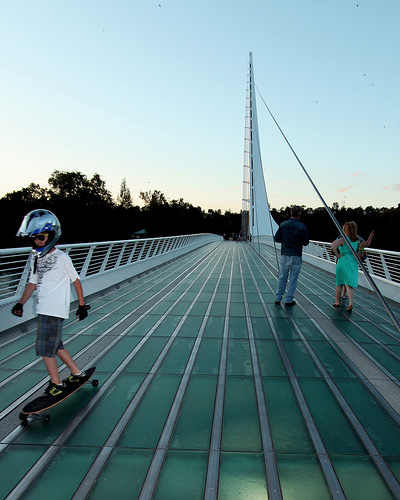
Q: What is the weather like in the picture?
A: It is clear.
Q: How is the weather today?
A: It is clear.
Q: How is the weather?
A: It is clear.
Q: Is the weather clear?
A: Yes, it is clear.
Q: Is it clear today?
A: Yes, it is clear.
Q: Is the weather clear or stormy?
A: It is clear.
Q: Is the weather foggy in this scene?
A: No, it is clear.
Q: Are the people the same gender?
A: No, they are both male and female.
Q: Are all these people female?
A: No, they are both male and female.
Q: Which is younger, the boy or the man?
A: The boy is younger than the man.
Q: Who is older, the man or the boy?
A: The man is older than the boy.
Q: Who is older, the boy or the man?
A: The man is older than the boy.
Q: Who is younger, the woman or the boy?
A: The boy is younger than the woman.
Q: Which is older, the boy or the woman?
A: The woman is older than the boy.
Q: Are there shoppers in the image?
A: No, there are no shoppers.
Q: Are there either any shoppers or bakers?
A: No, there are no shoppers or bakers.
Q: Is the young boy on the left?
A: Yes, the boy is on the left of the image.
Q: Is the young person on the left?
A: Yes, the boy is on the left of the image.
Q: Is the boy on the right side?
A: No, the boy is on the left of the image.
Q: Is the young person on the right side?
A: No, the boy is on the left of the image.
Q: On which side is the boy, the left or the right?
A: The boy is on the left of the image.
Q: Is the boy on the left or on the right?
A: The boy is on the left of the image.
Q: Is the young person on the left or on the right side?
A: The boy is on the left of the image.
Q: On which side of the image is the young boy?
A: The boy is on the left of the image.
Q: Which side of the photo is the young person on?
A: The boy is on the left of the image.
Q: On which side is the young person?
A: The boy is on the left of the image.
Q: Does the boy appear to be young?
A: Yes, the boy is young.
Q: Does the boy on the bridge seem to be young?
A: Yes, the boy is young.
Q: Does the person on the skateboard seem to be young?
A: Yes, the boy is young.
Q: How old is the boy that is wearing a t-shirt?
A: The boy is young.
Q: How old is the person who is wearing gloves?
A: The boy is young.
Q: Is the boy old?
A: No, the boy is young.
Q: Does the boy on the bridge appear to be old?
A: No, the boy is young.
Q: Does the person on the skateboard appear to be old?
A: No, the boy is young.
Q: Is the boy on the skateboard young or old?
A: The boy is young.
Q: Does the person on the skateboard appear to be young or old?
A: The boy is young.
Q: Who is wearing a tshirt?
A: The boy is wearing a tshirt.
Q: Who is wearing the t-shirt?
A: The boy is wearing a tshirt.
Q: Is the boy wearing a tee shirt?
A: Yes, the boy is wearing a tee shirt.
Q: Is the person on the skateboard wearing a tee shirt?
A: Yes, the boy is wearing a tee shirt.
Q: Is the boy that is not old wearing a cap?
A: No, the boy is wearing a tee shirt.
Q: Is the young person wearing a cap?
A: No, the boy is wearing a tee shirt.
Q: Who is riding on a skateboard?
A: The boy is riding on a skateboard.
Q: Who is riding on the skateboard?
A: The boy is riding on a skateboard.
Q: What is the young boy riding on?
A: The boy is riding on a skateboard.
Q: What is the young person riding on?
A: The boy is riding on a skateboard.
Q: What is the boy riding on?
A: The boy is riding on a skateboard.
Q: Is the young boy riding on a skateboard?
A: Yes, the boy is riding on a skateboard.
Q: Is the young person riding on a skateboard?
A: Yes, the boy is riding on a skateboard.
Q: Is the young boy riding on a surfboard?
A: No, the boy is riding on a skateboard.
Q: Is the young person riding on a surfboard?
A: No, the boy is riding on a skateboard.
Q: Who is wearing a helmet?
A: The boy is wearing a helmet.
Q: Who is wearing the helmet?
A: The boy is wearing a helmet.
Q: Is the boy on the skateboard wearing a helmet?
A: Yes, the boy is wearing a helmet.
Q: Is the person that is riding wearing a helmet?
A: Yes, the boy is wearing a helmet.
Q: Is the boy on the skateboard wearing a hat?
A: No, the boy is wearing a helmet.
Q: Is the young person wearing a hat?
A: No, the boy is wearing a helmet.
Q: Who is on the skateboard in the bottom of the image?
A: The boy is on the skateboard.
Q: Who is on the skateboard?
A: The boy is on the skateboard.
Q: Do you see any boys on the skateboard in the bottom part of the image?
A: Yes, there is a boy on the skateboard.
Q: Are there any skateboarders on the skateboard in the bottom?
A: No, there is a boy on the skateboard.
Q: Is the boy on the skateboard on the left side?
A: Yes, the boy is on the skateboard.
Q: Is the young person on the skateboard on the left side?
A: Yes, the boy is on the skateboard.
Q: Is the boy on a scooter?
A: No, the boy is on the skateboard.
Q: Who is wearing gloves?
A: The boy is wearing gloves.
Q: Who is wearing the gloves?
A: The boy is wearing gloves.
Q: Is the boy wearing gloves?
A: Yes, the boy is wearing gloves.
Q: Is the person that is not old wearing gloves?
A: Yes, the boy is wearing gloves.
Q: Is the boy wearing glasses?
A: No, the boy is wearing gloves.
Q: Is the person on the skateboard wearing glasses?
A: No, the boy is wearing gloves.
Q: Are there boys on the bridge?
A: Yes, there is a boy on the bridge.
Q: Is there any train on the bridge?
A: No, there is a boy on the bridge.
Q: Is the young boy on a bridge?
A: Yes, the boy is on a bridge.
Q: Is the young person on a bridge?
A: Yes, the boy is on a bridge.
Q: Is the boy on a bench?
A: No, the boy is on a bridge.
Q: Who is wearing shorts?
A: The boy is wearing shorts.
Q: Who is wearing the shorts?
A: The boy is wearing shorts.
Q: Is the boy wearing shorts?
A: Yes, the boy is wearing shorts.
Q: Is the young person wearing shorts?
A: Yes, the boy is wearing shorts.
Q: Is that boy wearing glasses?
A: No, the boy is wearing shorts.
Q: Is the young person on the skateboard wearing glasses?
A: No, the boy is wearing shorts.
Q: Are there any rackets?
A: No, there are no rackets.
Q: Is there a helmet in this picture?
A: Yes, there is a helmet.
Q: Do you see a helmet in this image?
A: Yes, there is a helmet.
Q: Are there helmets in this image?
A: Yes, there is a helmet.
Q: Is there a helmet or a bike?
A: Yes, there is a helmet.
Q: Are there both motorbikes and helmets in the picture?
A: No, there is a helmet but no motorcycles.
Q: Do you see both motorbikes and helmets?
A: No, there is a helmet but no motorcycles.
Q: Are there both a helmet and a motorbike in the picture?
A: No, there is a helmet but no motorcycles.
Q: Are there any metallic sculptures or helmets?
A: Yes, there is a metal helmet.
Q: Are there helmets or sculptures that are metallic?
A: Yes, the helmet is metallic.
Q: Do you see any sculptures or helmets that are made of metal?
A: Yes, the helmet is made of metal.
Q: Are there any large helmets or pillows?
A: Yes, there is a large helmet.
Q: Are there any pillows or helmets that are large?
A: Yes, the helmet is large.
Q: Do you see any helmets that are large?
A: Yes, there is a large helmet.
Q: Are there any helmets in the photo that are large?
A: Yes, there is a helmet that is large.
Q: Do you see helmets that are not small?
A: Yes, there is a large helmet.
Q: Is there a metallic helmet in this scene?
A: Yes, there is a metal helmet.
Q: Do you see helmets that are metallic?
A: Yes, there is a helmet that is metallic.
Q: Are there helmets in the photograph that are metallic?
A: Yes, there is a helmet that is metallic.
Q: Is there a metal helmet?
A: Yes, there is a helmet that is made of metal.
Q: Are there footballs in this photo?
A: No, there are no footballs.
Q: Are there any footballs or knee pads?
A: No, there are no footballs or knee pads.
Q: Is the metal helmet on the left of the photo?
A: Yes, the helmet is on the left of the image.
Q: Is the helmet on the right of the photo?
A: No, the helmet is on the left of the image.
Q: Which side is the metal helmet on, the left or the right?
A: The helmet is on the left of the image.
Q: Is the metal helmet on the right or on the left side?
A: The helmet is on the left of the image.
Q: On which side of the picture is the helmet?
A: The helmet is on the left of the image.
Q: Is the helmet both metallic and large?
A: Yes, the helmet is metallic and large.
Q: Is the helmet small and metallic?
A: No, the helmet is metallic but large.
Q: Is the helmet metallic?
A: Yes, the helmet is metallic.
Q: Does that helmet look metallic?
A: Yes, the helmet is metallic.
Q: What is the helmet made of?
A: The helmet is made of metal.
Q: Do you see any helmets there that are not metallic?
A: No, there is a helmet but it is metallic.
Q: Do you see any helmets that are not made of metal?
A: No, there is a helmet but it is made of metal.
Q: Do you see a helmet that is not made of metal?
A: No, there is a helmet but it is made of metal.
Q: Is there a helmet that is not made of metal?
A: No, there is a helmet but it is made of metal.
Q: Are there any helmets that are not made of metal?
A: No, there is a helmet but it is made of metal.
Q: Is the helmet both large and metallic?
A: Yes, the helmet is large and metallic.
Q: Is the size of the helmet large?
A: Yes, the helmet is large.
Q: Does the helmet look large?
A: Yes, the helmet is large.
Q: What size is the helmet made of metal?
A: The helmet is large.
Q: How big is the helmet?
A: The helmet is large.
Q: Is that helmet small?
A: No, the helmet is large.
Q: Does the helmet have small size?
A: No, the helmet is large.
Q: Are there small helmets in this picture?
A: No, there is a helmet but it is large.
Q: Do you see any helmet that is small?
A: No, there is a helmet but it is large.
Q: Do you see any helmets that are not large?
A: No, there is a helmet but it is large.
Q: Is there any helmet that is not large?
A: No, there is a helmet but it is large.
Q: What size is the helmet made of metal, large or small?
A: The helmet is large.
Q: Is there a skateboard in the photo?
A: Yes, there is a skateboard.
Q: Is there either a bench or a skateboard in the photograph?
A: Yes, there is a skateboard.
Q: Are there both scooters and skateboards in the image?
A: No, there is a skateboard but no scooters.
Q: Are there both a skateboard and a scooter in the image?
A: No, there is a skateboard but no scooters.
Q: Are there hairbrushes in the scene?
A: No, there are no hairbrushes.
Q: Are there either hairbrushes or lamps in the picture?
A: No, there are no hairbrushes or lamps.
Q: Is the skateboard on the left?
A: Yes, the skateboard is on the left of the image.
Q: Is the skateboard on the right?
A: No, the skateboard is on the left of the image.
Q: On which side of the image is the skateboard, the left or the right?
A: The skateboard is on the left of the image.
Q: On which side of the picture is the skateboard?
A: The skateboard is on the left of the image.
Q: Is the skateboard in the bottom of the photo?
A: Yes, the skateboard is in the bottom of the image.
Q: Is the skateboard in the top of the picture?
A: No, the skateboard is in the bottom of the image.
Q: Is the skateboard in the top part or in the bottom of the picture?
A: The skateboard is in the bottom of the image.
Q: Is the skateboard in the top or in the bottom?
A: The skateboard is in the bottom of the image.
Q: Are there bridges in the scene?
A: Yes, there is a bridge.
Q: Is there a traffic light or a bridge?
A: Yes, there is a bridge.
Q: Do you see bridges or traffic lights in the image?
A: Yes, there is a bridge.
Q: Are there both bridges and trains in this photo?
A: No, there is a bridge but no trains.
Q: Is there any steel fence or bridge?
A: Yes, there is a steel bridge.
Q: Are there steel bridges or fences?
A: Yes, there is a steel bridge.